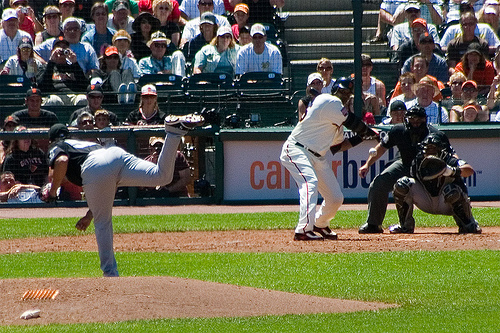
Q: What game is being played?
A: Baseball.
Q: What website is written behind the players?
A: Careerbuilder.com.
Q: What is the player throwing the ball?
A: Pitcher.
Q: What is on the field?
A: Grass.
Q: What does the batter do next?
A: Run.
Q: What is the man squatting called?
A: Catcher.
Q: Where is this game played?
A: Stadium.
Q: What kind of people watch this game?
A: Baseball fans.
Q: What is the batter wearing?
A: A baseball uniform.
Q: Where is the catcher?
A: Kneeling by home plate.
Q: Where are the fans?
A: In the stands.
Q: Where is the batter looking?
A: At the ball.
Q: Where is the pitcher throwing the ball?
A: The catcher's glove.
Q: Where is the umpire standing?
A: Behind the catcher.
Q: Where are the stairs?
A: Next to the bleachers.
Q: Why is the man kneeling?
A: Catching the ball.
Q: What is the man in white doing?
A: Hitting the ball.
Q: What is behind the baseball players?
A: Men and women.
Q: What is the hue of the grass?
A: Green.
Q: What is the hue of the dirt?
A: Brown.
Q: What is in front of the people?
A: Safety netting.